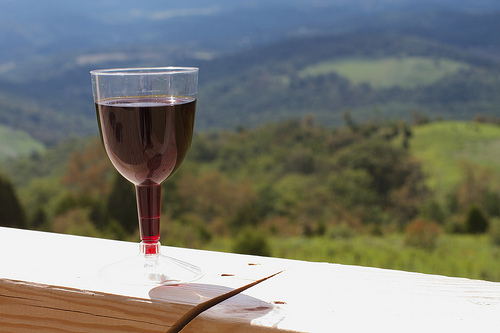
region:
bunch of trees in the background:
[276, 145, 308, 168]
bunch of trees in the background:
[246, 167, 271, 204]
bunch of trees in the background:
[256, 90, 280, 115]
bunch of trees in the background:
[35, 92, 66, 126]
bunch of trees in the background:
[65, 167, 94, 198]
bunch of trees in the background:
[20, 167, 51, 195]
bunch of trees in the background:
[399, 220, 431, 248]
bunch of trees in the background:
[456, 81, 470, 104]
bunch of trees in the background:
[403, 101, 433, 127]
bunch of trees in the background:
[373, 28, 405, 55]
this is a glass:
[129, 104, 174, 169]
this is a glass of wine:
[89, 110, 91, 112]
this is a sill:
[18, 235, 153, 311]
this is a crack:
[200, 293, 220, 305]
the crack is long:
[185, 289, 197, 311]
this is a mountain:
[236, 17, 278, 68]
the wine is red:
[149, 111, 209, 199]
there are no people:
[20, 228, 164, 305]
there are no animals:
[85, 192, 105, 237]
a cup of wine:
[80, 52, 210, 292]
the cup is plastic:
[80, 57, 219, 301]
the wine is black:
[87, 95, 207, 257]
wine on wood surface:
[2, 55, 491, 330]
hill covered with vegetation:
[210, 26, 497, 121]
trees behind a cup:
[11, 10, 496, 229]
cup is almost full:
[80, 55, 211, 290]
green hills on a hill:
[225, 105, 496, 265]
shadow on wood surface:
[133, 270, 279, 330]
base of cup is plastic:
[86, 250, 205, 290]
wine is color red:
[83, 56, 215, 293]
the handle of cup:
[131, 179, 167, 256]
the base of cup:
[94, 247, 210, 292]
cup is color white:
[76, 54, 210, 291]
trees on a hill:
[206, 112, 498, 259]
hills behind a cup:
[9, 10, 496, 245]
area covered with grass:
[288, 47, 479, 99]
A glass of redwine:
[88, 55, 215, 300]